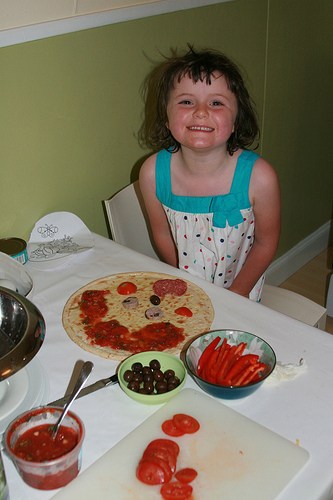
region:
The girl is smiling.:
[121, 42, 285, 278]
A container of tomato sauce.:
[1, 399, 83, 479]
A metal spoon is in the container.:
[44, 353, 88, 436]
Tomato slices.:
[130, 407, 221, 492]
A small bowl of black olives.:
[113, 342, 183, 401]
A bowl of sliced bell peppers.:
[182, 323, 272, 395]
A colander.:
[0, 283, 44, 386]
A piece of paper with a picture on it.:
[27, 196, 92, 270]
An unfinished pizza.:
[61, 263, 214, 358]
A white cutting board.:
[103, 394, 308, 496]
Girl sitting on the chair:
[138, 42, 280, 302]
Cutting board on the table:
[48, 387, 311, 499]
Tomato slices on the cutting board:
[135, 412, 199, 498]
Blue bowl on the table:
[184, 327, 274, 397]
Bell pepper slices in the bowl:
[194, 334, 263, 383]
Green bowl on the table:
[117, 351, 187, 402]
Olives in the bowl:
[123, 357, 178, 393]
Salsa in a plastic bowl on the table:
[7, 405, 84, 489]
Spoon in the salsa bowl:
[49, 359, 93, 438]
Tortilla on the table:
[61, 270, 213, 358]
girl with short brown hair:
[100, 35, 284, 282]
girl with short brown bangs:
[137, 29, 272, 245]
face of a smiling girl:
[144, 59, 232, 154]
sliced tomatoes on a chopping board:
[123, 396, 220, 497]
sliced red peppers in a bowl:
[197, 327, 275, 387]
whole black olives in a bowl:
[121, 351, 187, 397]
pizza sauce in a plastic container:
[13, 356, 100, 475]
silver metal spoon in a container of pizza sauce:
[35, 347, 105, 444]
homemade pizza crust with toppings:
[68, 250, 207, 357]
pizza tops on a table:
[25, 317, 277, 492]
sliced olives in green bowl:
[115, 353, 183, 402]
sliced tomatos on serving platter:
[133, 411, 203, 499]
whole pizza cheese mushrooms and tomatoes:
[73, 270, 204, 357]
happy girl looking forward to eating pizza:
[123, 37, 265, 197]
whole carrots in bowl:
[186, 329, 279, 399]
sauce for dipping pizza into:
[6, 399, 89, 488]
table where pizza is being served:
[3, 222, 313, 497]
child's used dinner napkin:
[270, 351, 311, 393]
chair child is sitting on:
[102, 160, 326, 344]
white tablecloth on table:
[4, 231, 327, 499]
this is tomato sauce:
[3, 403, 90, 491]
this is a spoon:
[41, 356, 96, 446]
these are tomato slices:
[124, 409, 213, 499]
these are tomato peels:
[199, 337, 257, 389]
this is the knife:
[26, 357, 133, 418]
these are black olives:
[131, 356, 184, 394]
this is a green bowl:
[115, 348, 184, 409]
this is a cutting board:
[36, 380, 313, 498]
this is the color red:
[28, 440, 35, 445]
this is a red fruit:
[137, 407, 208, 499]